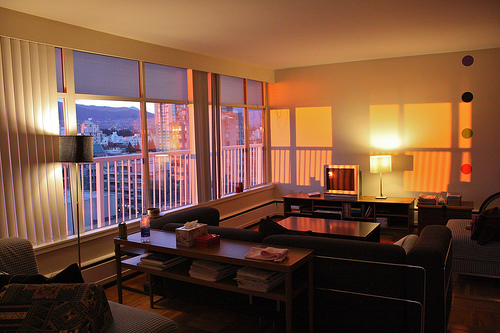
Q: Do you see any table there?
A: Yes, there is a table.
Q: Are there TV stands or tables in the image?
A: Yes, there is a table.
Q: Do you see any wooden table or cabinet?
A: Yes, there is a wood table.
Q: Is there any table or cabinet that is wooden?
A: Yes, the table is wooden.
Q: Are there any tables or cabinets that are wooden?
A: Yes, the table is wooden.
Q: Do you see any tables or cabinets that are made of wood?
A: Yes, the table is made of wood.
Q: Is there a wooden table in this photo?
A: Yes, there is a wood table.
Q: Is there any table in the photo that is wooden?
A: Yes, there is a table that is wooden.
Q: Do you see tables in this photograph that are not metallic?
A: Yes, there is a wooden table.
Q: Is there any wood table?
A: Yes, there is a table that is made of wood.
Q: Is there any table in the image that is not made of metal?
A: Yes, there is a table that is made of wood.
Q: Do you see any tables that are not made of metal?
A: Yes, there is a table that is made of wood.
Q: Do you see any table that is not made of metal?
A: Yes, there is a table that is made of wood.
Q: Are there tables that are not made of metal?
A: Yes, there is a table that is made of wood.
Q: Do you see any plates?
A: No, there are no plates.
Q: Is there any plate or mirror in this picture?
A: No, there are no plates or mirrors.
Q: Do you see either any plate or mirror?
A: No, there are no plates or mirrors.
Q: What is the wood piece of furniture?
A: The piece of furniture is a table.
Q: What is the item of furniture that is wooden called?
A: The piece of furniture is a table.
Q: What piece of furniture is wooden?
A: The piece of furniture is a table.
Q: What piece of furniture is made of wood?
A: The piece of furniture is a table.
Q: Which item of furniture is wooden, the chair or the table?
A: The table is wooden.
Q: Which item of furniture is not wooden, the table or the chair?
A: The chair is not wooden.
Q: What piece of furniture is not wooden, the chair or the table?
A: The chair is not wooden.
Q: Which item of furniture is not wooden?
A: The piece of furniture is a chair.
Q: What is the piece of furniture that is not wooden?
A: The piece of furniture is a chair.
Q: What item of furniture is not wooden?
A: The piece of furniture is a chair.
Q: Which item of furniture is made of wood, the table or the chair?
A: The table is made of wood.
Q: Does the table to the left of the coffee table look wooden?
A: Yes, the table is wooden.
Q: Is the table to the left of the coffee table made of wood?
A: Yes, the table is made of wood.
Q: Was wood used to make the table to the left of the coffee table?
A: Yes, the table is made of wood.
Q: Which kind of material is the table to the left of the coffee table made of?
A: The table is made of wood.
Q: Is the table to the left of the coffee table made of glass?
A: No, the table is made of wood.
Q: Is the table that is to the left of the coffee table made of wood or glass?
A: The table is made of wood.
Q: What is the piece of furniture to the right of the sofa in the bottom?
A: The piece of furniture is a table.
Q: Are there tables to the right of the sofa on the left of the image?
A: Yes, there is a table to the right of the sofa.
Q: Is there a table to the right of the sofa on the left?
A: Yes, there is a table to the right of the sofa.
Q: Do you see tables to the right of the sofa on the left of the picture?
A: Yes, there is a table to the right of the sofa.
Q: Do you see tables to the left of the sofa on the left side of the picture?
A: No, the table is to the right of the sofa.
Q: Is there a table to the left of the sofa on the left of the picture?
A: No, the table is to the right of the sofa.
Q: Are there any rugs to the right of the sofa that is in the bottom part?
A: No, there is a table to the right of the sofa.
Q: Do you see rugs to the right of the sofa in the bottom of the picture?
A: No, there is a table to the right of the sofa.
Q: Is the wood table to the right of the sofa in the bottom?
A: Yes, the table is to the right of the sofa.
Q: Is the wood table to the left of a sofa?
A: No, the table is to the right of a sofa.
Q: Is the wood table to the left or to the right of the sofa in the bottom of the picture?
A: The table is to the right of the sofa.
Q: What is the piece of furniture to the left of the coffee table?
A: The piece of furniture is a table.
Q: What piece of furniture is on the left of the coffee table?
A: The piece of furniture is a table.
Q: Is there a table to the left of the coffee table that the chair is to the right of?
A: Yes, there is a table to the left of the coffee table.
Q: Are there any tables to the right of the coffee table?
A: No, the table is to the left of the coffee table.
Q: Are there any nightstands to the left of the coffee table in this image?
A: No, there is a table to the left of the coffee table.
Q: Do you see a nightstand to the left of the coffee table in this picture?
A: No, there is a table to the left of the coffee table.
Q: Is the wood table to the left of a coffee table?
A: Yes, the table is to the left of a coffee table.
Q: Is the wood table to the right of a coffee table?
A: No, the table is to the left of a coffee table.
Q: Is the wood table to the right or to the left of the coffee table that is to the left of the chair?
A: The table is to the left of the coffee table.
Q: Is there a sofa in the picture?
A: Yes, there is a sofa.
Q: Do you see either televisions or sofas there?
A: Yes, there is a sofa.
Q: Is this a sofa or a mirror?
A: This is a sofa.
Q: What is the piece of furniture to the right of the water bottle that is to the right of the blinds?
A: The piece of furniture is a sofa.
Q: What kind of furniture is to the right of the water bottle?
A: The piece of furniture is a sofa.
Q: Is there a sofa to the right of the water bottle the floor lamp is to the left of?
A: Yes, there is a sofa to the right of the water bottle.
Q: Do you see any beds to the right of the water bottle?
A: No, there is a sofa to the right of the water bottle.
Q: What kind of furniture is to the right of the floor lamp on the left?
A: The piece of furniture is a sofa.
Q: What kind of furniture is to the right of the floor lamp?
A: The piece of furniture is a sofa.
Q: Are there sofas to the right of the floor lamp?
A: Yes, there is a sofa to the right of the floor lamp.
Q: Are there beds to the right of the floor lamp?
A: No, there is a sofa to the right of the floor lamp.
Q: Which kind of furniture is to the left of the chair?
A: The piece of furniture is a sofa.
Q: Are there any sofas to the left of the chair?
A: Yes, there is a sofa to the left of the chair.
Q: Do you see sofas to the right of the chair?
A: No, the sofa is to the left of the chair.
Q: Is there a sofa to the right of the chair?
A: No, the sofa is to the left of the chair.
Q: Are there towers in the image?
A: No, there are no towers.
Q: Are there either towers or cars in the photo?
A: No, there are no towers or cars.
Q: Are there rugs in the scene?
A: No, there are no rugs.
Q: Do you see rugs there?
A: No, there are no rugs.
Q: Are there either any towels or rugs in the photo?
A: No, there are no rugs or towels.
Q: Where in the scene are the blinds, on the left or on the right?
A: The blinds are on the left of the image.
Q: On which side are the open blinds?
A: The blinds are on the left of the image.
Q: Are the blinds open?
A: Yes, the blinds are open.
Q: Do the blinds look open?
A: Yes, the blinds are open.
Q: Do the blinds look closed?
A: No, the blinds are open.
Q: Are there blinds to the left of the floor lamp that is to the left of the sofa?
A: Yes, there are blinds to the left of the floor lamp.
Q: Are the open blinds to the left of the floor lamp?
A: Yes, the blinds are to the left of the floor lamp.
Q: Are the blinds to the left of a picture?
A: No, the blinds are to the left of the floor lamp.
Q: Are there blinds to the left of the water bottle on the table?
A: Yes, there are blinds to the left of the water bottle.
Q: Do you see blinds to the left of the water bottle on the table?
A: Yes, there are blinds to the left of the water bottle.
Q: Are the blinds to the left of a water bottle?
A: Yes, the blinds are to the left of a water bottle.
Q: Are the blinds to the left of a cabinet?
A: No, the blinds are to the left of a water bottle.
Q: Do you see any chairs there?
A: Yes, there is a chair.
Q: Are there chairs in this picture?
A: Yes, there is a chair.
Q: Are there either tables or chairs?
A: Yes, there is a chair.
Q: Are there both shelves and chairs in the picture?
A: Yes, there are both a chair and a shelf.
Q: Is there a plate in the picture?
A: No, there are no plates.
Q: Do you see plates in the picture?
A: No, there are no plates.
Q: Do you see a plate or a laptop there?
A: No, there are no plates or laptops.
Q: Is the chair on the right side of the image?
A: Yes, the chair is on the right of the image.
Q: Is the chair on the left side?
A: No, the chair is on the right of the image.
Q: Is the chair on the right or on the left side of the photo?
A: The chair is on the right of the image.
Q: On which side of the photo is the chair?
A: The chair is on the right of the image.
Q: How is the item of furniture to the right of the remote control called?
A: The piece of furniture is a chair.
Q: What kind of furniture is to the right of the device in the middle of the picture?
A: The piece of furniture is a chair.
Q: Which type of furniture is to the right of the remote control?
A: The piece of furniture is a chair.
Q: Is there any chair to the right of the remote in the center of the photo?
A: Yes, there is a chair to the right of the remote.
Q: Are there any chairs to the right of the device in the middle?
A: Yes, there is a chair to the right of the remote.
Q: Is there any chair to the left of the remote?
A: No, the chair is to the right of the remote.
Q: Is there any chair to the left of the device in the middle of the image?
A: No, the chair is to the right of the remote.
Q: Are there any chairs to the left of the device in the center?
A: No, the chair is to the right of the remote.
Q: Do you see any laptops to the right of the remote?
A: No, there is a chair to the right of the remote.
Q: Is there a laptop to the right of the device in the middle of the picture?
A: No, there is a chair to the right of the remote.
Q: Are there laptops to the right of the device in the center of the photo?
A: No, there is a chair to the right of the remote.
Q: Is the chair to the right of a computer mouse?
A: No, the chair is to the right of the remote control.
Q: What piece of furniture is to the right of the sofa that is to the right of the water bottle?
A: The piece of furniture is a chair.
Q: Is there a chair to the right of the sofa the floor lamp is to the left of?
A: Yes, there is a chair to the right of the sofa.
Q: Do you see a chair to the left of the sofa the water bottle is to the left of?
A: No, the chair is to the right of the sofa.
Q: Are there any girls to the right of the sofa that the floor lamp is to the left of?
A: No, there is a chair to the right of the sofa.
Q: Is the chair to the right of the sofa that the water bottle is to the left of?
A: Yes, the chair is to the right of the sofa.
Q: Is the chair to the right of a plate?
A: No, the chair is to the right of the sofa.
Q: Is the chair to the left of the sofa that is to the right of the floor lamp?
A: No, the chair is to the right of the sofa.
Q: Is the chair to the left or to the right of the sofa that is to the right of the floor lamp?
A: The chair is to the right of the sofa.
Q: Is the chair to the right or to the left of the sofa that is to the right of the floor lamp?
A: The chair is to the right of the sofa.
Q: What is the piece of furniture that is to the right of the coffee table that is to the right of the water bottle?
A: The piece of furniture is a chair.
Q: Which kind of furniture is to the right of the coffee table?
A: The piece of furniture is a chair.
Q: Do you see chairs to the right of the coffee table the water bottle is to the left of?
A: Yes, there is a chair to the right of the coffee table.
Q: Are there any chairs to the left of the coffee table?
A: No, the chair is to the right of the coffee table.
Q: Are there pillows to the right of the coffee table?
A: No, there is a chair to the right of the coffee table.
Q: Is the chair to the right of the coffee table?
A: Yes, the chair is to the right of the coffee table.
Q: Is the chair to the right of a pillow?
A: No, the chair is to the right of the coffee table.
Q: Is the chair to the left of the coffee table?
A: No, the chair is to the right of the coffee table.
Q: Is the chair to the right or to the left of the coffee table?
A: The chair is to the right of the coffee table.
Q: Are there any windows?
A: Yes, there is a window.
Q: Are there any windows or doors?
A: Yes, there is a window.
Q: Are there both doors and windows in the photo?
A: No, there is a window but no doors.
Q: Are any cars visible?
A: No, there are no cars.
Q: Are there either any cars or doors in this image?
A: No, there are no cars or doors.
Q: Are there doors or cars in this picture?
A: No, there are no cars or doors.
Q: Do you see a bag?
A: No, there are no bags.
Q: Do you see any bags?
A: No, there are no bags.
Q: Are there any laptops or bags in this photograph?
A: No, there are no bags or laptops.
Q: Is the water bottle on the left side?
A: Yes, the water bottle is on the left of the image.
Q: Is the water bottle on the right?
A: No, the water bottle is on the left of the image.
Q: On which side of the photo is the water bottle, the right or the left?
A: The water bottle is on the left of the image.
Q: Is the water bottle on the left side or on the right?
A: The water bottle is on the left of the image.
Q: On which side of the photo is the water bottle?
A: The water bottle is on the left of the image.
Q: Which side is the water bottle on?
A: The water bottle is on the left of the image.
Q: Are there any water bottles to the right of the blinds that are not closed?
A: Yes, there is a water bottle to the right of the blinds.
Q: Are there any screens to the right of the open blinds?
A: No, there is a water bottle to the right of the blinds.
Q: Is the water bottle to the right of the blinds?
A: Yes, the water bottle is to the right of the blinds.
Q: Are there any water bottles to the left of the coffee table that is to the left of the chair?
A: Yes, there is a water bottle to the left of the coffee table.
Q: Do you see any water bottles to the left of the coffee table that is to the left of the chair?
A: Yes, there is a water bottle to the left of the coffee table.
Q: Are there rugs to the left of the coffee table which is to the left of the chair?
A: No, there is a water bottle to the left of the coffee table.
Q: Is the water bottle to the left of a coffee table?
A: Yes, the water bottle is to the left of a coffee table.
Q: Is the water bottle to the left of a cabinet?
A: No, the water bottle is to the left of a coffee table.